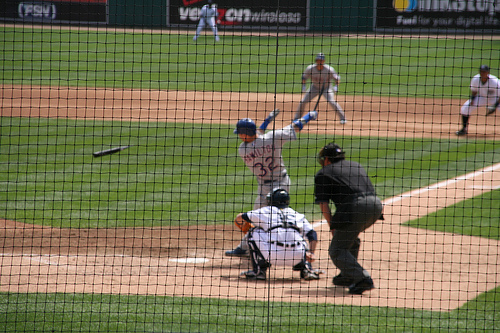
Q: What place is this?
A: It is a field.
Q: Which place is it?
A: It is a field.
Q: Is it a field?
A: Yes, it is a field.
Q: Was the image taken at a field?
A: Yes, it was taken in a field.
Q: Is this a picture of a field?
A: Yes, it is showing a field.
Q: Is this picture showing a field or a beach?
A: It is showing a field.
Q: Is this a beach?
A: No, it is a field.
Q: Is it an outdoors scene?
A: Yes, it is outdoors.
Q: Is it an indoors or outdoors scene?
A: It is outdoors.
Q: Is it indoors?
A: No, it is outdoors.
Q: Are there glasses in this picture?
A: No, there are no glasses.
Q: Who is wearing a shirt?
A: The catcher is wearing a shirt.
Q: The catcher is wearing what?
A: The catcher is wearing a shirt.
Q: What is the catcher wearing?
A: The catcher is wearing a shirt.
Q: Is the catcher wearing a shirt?
A: Yes, the catcher is wearing a shirt.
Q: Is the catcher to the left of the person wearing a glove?
A: No, the catcher is wearing a shirt.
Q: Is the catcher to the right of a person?
A: No, the catcher is to the left of a person.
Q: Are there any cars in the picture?
A: No, there are no cars.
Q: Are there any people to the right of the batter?
A: Yes, there is a person to the right of the batter.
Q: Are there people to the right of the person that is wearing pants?
A: Yes, there is a person to the right of the batter.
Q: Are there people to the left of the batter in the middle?
A: No, the person is to the right of the batter.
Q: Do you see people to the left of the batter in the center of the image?
A: No, the person is to the right of the batter.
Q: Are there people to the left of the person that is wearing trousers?
A: No, the person is to the right of the batter.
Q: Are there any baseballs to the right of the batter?
A: No, there is a person to the right of the batter.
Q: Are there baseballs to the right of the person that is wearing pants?
A: No, there is a person to the right of the batter.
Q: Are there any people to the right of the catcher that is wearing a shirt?
A: Yes, there is a person to the right of the catcher.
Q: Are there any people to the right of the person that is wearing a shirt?
A: Yes, there is a person to the right of the catcher.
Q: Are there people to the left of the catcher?
A: No, the person is to the right of the catcher.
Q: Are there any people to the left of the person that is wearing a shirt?
A: No, the person is to the right of the catcher.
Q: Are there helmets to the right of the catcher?
A: No, there is a person to the right of the catcher.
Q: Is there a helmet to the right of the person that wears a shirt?
A: No, there is a person to the right of the catcher.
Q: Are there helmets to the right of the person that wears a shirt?
A: No, there is a person to the right of the catcher.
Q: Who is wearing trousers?
A: The batter is wearing trousers.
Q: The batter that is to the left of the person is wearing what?
A: The batter is wearing trousers.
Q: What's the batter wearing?
A: The batter is wearing trousers.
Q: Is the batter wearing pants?
A: Yes, the batter is wearing pants.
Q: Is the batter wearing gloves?
A: No, the batter is wearing pants.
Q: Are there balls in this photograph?
A: No, there are no balls.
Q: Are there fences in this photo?
A: Yes, there is a fence.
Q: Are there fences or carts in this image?
A: Yes, there is a fence.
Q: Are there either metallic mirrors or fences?
A: Yes, there is a metal fence.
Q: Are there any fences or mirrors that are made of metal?
A: Yes, the fence is made of metal.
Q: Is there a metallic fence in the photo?
A: Yes, there is a metal fence.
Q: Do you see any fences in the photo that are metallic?
A: Yes, there is a fence that is metallic.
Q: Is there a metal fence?
A: Yes, there is a fence that is made of metal.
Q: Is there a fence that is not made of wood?
A: Yes, there is a fence that is made of metal.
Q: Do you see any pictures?
A: No, there are no pictures.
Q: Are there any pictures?
A: No, there are no pictures.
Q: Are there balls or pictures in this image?
A: No, there are no pictures or balls.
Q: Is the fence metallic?
A: Yes, the fence is metallic.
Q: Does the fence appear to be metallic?
A: Yes, the fence is metallic.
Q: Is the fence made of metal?
A: Yes, the fence is made of metal.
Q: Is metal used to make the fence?
A: Yes, the fence is made of metal.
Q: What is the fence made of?
A: The fence is made of metal.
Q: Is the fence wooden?
A: No, the fence is metallic.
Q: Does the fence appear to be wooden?
A: No, the fence is metallic.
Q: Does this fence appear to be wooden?
A: No, the fence is metallic.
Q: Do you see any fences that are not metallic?
A: No, there is a fence but it is metallic.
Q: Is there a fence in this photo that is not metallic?
A: No, there is a fence but it is metallic.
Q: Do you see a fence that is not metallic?
A: No, there is a fence but it is metallic.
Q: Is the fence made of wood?
A: No, the fence is made of metal.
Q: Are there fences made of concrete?
A: No, there is a fence but it is made of metal.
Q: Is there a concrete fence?
A: No, there is a fence but it is made of metal.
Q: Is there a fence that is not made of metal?
A: No, there is a fence but it is made of metal.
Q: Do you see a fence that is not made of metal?
A: No, there is a fence but it is made of metal.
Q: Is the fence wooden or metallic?
A: The fence is metallic.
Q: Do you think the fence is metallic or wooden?
A: The fence is metallic.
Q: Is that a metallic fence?
A: Yes, that is a metallic fence.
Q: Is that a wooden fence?
A: No, that is a metallic fence.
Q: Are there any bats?
A: Yes, there is a bat.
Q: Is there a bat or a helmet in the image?
A: Yes, there is a bat.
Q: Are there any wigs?
A: No, there are no wigs.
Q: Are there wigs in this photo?
A: No, there are no wigs.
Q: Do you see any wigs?
A: No, there are no wigs.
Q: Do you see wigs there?
A: No, there are no wigs.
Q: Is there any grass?
A: Yes, there is grass.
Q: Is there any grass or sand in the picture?
A: Yes, there is grass.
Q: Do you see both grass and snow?
A: No, there is grass but no snow.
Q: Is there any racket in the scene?
A: No, there are no rackets.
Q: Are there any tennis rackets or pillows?
A: No, there are no tennis rackets or pillows.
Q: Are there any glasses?
A: No, there are no glasses.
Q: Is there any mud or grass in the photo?
A: Yes, there is grass.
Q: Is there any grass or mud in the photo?
A: Yes, there is grass.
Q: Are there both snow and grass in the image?
A: No, there is grass but no snow.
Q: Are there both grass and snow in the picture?
A: No, there is grass but no snow.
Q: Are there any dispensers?
A: No, there are no dispensers.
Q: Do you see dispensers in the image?
A: No, there are no dispensers.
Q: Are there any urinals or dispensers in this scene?
A: No, there are no dispensers or urinals.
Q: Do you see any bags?
A: No, there are no bags.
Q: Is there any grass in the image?
A: Yes, there is grass.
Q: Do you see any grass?
A: Yes, there is grass.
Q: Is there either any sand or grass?
A: Yes, there is grass.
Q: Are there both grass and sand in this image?
A: No, there is grass but no sand.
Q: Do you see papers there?
A: No, there are no papers.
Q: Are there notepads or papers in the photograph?
A: No, there are no papers or notepads.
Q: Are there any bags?
A: No, there are no bags.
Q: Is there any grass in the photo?
A: Yes, there is grass.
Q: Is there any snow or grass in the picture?
A: Yes, there is grass.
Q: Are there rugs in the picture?
A: No, there are no rugs.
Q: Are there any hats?
A: Yes, there is a hat.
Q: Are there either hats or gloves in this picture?
A: Yes, there is a hat.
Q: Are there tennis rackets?
A: No, there are no tennis rackets.